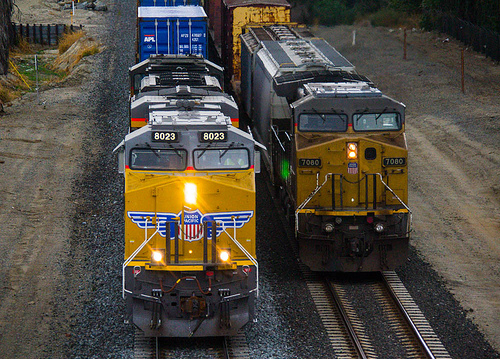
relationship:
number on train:
[298, 156, 321, 169] [204, 0, 409, 277]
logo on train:
[126, 208, 255, 243] [100, 119, 311, 354]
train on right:
[273, 58, 451, 313] [245, 5, 448, 327]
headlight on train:
[184, 183, 197, 203] [110, 1, 260, 341]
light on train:
[218, 249, 232, 262] [110, 1, 260, 341]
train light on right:
[345, 141, 360, 160] [276, 9, 463, 328]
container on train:
[135, 3, 208, 63] [108, 51, 268, 357]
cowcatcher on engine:
[120, 262, 257, 339] [110, 50, 270, 338]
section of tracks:
[291, 272, 339, 352] [305, 268, 451, 357]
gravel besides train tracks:
[405, 274, 442, 309] [133, 339, 478, 349]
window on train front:
[191, 146, 251, 170] [112, 120, 267, 339]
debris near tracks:
[24, 17, 110, 100] [290, 253, 394, 355]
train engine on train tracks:
[291, 92, 415, 277] [259, 276, 500, 358]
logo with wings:
[122, 206, 254, 243] [123, 193, 316, 294]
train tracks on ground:
[319, 302, 444, 342] [406, 266, 473, 342]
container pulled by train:
[135, 5, 209, 63] [108, 0, 268, 344]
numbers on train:
[150, 129, 177, 142] [242, 23, 407, 273]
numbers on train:
[150, 132, 227, 146] [103, 81, 269, 356]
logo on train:
[126, 208, 255, 243] [110, 1, 260, 341]